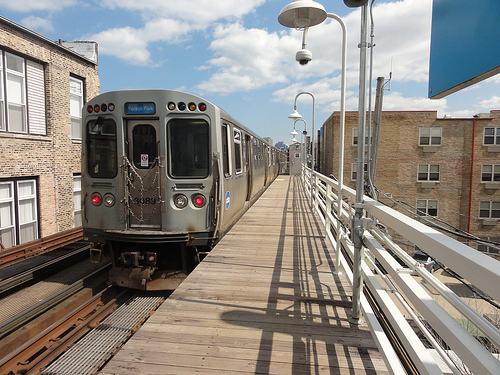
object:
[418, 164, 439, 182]
window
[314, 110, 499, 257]
building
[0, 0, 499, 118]
clouds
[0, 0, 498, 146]
sky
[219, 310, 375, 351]
shadow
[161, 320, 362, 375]
ground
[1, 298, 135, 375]
ground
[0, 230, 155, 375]
train tracks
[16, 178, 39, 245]
window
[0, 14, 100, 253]
building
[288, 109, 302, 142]
street light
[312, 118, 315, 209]
pole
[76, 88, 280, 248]
train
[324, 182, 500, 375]
railing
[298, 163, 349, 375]
platform